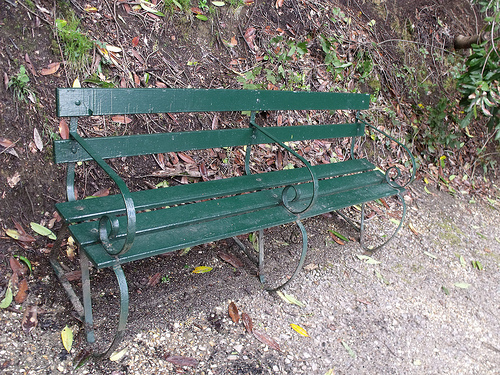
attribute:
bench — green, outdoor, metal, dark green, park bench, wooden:
[55, 84, 414, 357]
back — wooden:
[56, 88, 370, 160]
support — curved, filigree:
[87, 266, 129, 361]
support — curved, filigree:
[267, 220, 310, 292]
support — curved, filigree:
[365, 195, 407, 253]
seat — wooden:
[50, 158, 405, 266]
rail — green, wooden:
[55, 87, 370, 111]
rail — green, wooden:
[54, 124, 365, 164]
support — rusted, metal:
[45, 220, 96, 345]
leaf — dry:
[59, 120, 69, 140]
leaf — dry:
[179, 151, 195, 165]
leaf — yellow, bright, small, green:
[192, 265, 213, 275]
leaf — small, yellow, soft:
[290, 320, 309, 337]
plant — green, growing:
[425, 101, 466, 172]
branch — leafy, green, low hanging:
[455, 1, 499, 126]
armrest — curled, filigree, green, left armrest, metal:
[70, 132, 136, 257]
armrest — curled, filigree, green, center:
[251, 121, 319, 214]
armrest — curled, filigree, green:
[358, 118, 417, 189]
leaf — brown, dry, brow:
[228, 300, 240, 326]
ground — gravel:
[0, 176, 497, 374]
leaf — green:
[0, 286, 16, 308]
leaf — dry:
[242, 312, 280, 351]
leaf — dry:
[328, 229, 345, 246]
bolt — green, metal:
[75, 100, 82, 108]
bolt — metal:
[72, 145, 79, 154]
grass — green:
[417, 98, 449, 132]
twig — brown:
[49, 1, 72, 86]